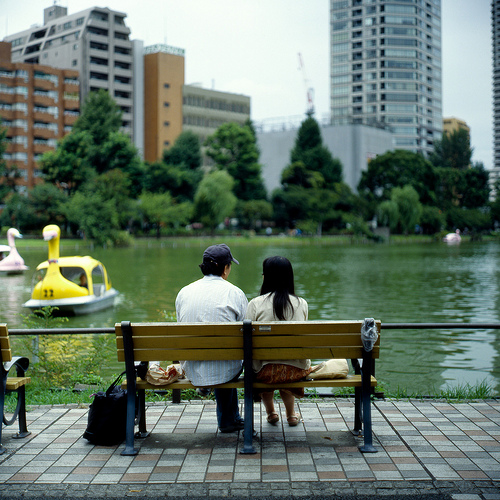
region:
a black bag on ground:
[82, 362, 130, 444]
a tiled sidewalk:
[1, 395, 491, 485]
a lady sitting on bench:
[241, 256, 308, 426]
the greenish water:
[1, 231, 493, 391]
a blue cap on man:
[200, 237, 237, 262]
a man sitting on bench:
[175, 238, 251, 435]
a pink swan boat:
[0, 218, 28, 273]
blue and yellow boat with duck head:
[21, 216, 121, 325]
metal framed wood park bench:
[109, 312, 385, 452]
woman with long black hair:
[244, 253, 318, 427]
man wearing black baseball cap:
[171, 241, 247, 440]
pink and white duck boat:
[1, 221, 33, 283]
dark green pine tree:
[270, 108, 357, 240]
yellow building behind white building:
[443, 108, 470, 143]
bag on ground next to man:
[81, 376, 145, 451]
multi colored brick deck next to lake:
[2, 391, 497, 496]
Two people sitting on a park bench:
[152, 233, 331, 432]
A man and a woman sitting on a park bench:
[161, 232, 332, 454]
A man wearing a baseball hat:
[163, 231, 254, 450]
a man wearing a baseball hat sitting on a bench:
[173, 232, 254, 444]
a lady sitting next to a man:
[171, 230, 330, 465]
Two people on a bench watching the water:
[116, 235, 382, 451]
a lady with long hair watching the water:
[245, 243, 335, 439]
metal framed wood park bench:
[103, 308, 389, 450]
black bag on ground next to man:
[81, 370, 149, 449]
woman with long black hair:
[246, 251, 314, 433]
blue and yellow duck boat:
[21, 215, 117, 324]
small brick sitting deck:
[3, 395, 499, 499]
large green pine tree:
[272, 117, 359, 236]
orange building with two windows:
[143, 116, 182, 174]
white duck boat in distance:
[442, 221, 465, 251]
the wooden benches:
[2, 318, 384, 453]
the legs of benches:
[3, 385, 382, 455]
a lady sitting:
[244, 248, 311, 430]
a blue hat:
[198, 240, 240, 267]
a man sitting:
[173, 238, 248, 443]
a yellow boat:
[20, 220, 122, 313]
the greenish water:
[0, 233, 497, 394]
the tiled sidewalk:
[3, 392, 498, 486]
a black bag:
[81, 368, 127, 447]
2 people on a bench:
[179, 242, 305, 446]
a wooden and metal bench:
[99, 320, 430, 451]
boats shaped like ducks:
[0, 220, 113, 354]